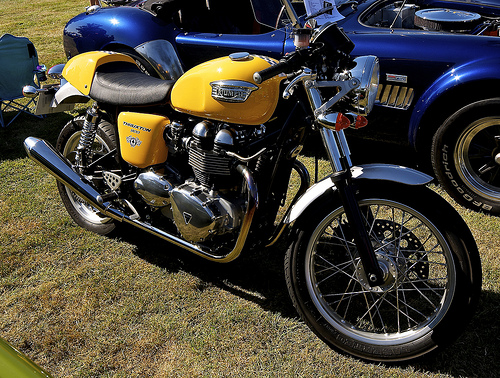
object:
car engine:
[377, 0, 499, 34]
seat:
[84, 66, 170, 108]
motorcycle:
[21, 4, 481, 361]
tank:
[170, 53, 284, 124]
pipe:
[24, 136, 125, 221]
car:
[63, 0, 500, 217]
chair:
[3, 32, 42, 132]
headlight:
[353, 56, 380, 116]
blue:
[85, 17, 150, 34]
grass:
[17, 227, 91, 275]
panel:
[209, 80, 259, 103]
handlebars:
[254, 57, 297, 85]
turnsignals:
[318, 112, 351, 131]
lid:
[414, 11, 482, 28]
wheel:
[418, 19, 480, 32]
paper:
[305, 3, 345, 24]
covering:
[426, 53, 498, 80]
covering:
[461, 119, 500, 132]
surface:
[0, 337, 52, 375]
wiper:
[301, 2, 349, 20]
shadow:
[134, 245, 181, 275]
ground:
[84, 272, 198, 344]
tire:
[280, 182, 480, 364]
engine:
[187, 120, 267, 189]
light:
[22, 86, 37, 98]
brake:
[358, 241, 408, 293]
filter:
[417, 7, 489, 31]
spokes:
[361, 276, 389, 332]